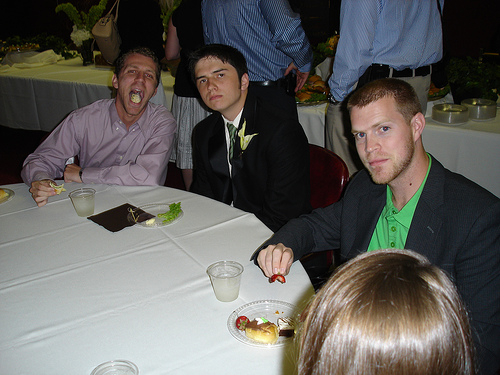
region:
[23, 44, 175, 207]
A man with his mouth open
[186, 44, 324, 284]
A dark haired man in a suit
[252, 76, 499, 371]
A man with a beard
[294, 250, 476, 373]
The back of a woman's head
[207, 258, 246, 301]
A small clear plastic cup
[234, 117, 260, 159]
A flower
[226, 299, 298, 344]
A plate of food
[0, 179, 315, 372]
A round table covered in a white cloth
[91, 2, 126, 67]
A tan shoulder bag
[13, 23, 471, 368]
several people sitting around a table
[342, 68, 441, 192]
a man with short brown hair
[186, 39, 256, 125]
a man with short black hair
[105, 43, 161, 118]
a man with his mouth open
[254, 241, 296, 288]
a hand with a half-eaten strawberry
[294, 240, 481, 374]
the brown hair on the back of a woman's head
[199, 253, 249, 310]
a plastic cup of water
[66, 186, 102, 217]
a plastic cup of water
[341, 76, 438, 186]
the head of a man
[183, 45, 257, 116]
the head of a man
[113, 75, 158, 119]
The man mouth is open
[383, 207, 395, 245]
Buttons on the shirt.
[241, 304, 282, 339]
Desserts on the plate.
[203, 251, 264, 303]
A clear cup on the table.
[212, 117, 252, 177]
The man is wearing a tie.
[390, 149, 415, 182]
The man has facial hair.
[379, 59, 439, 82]
The man is wearing a black belt.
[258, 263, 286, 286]
The man is holding a piece of strawberry.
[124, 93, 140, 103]
Food in the man mouth.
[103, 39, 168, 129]
this dude is awfully rude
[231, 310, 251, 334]
strawberry on a serving plate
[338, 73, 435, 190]
nice come-hither look from this guy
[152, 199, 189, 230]
only thing left on this plate is a bit of lettuce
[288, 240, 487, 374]
the boys have a female companion at the table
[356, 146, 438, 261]
this guy is wearing a light green polo shirt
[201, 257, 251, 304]
a plastic drink cup on the table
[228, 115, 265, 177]
this guy's boutonniere is a lily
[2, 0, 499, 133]
serving table in the background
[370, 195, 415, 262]
the shirt is green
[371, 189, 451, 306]
the shirt is green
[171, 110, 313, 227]
the coat is black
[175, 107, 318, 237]
the coat is black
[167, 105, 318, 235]
the coat is black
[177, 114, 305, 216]
the coat is black